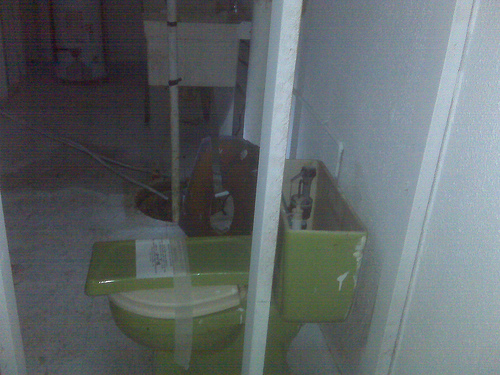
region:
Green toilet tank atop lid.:
[85, 233, 265, 295]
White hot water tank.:
[50, 0, 112, 87]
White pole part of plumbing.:
[163, 0, 180, 217]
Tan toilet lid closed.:
[110, 282, 245, 319]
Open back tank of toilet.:
[279, 152, 366, 245]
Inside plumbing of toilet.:
[292, 167, 318, 223]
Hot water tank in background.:
[51, 5, 109, 84]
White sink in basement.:
[135, 11, 239, 93]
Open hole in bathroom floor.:
[134, 177, 213, 224]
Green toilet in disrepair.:
[83, 159, 389, 374]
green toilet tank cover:
[81, 232, 266, 296]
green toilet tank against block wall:
[278, 151, 366, 329]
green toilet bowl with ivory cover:
[104, 290, 244, 350]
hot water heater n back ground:
[51, 3, 107, 86]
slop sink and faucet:
[147, 0, 254, 92]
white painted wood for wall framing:
[233, 0, 308, 371]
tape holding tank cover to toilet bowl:
[164, 233, 191, 368]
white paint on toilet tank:
[330, 228, 372, 323]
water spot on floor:
[1, 131, 163, 203]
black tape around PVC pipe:
[163, 13, 183, 94]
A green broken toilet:
[85, 148, 369, 373]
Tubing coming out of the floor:
[166, 0, 182, 225]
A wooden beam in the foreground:
[235, 1, 306, 373]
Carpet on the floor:
[0, 177, 171, 372]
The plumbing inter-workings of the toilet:
[281, 160, 323, 245]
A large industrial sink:
[142, 10, 243, 92]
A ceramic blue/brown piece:
[172, 129, 273, 244]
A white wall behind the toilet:
[287, 1, 499, 373]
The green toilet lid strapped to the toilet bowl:
[76, 225, 278, 298]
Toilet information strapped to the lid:
[128, 235, 193, 285]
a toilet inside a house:
[87, 109, 418, 318]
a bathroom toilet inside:
[65, 112, 364, 367]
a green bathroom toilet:
[39, 73, 414, 368]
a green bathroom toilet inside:
[89, 134, 336, 367]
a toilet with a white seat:
[44, 118, 311, 370]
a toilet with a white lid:
[69, 122, 369, 361]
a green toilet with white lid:
[104, 134, 453, 365]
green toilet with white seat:
[105, 168, 377, 370]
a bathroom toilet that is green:
[76, 126, 493, 342]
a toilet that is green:
[98, 125, 440, 372]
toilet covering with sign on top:
[86, 237, 261, 292]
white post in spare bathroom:
[250, 2, 297, 374]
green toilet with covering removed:
[108, 154, 368, 373]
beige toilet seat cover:
[106, 281, 240, 318]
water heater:
[49, 1, 108, 82]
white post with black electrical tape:
[167, 4, 182, 226]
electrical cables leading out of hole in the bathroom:
[1, 105, 171, 200]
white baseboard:
[283, 313, 330, 372]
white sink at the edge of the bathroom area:
[143, 0, 248, 90]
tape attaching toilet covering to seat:
[172, 240, 192, 374]